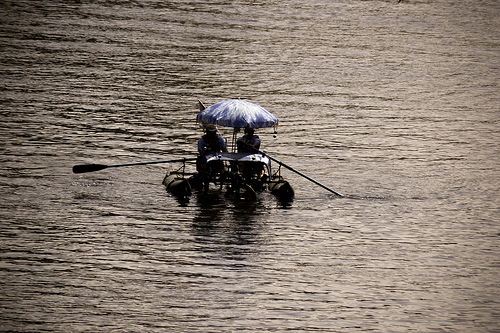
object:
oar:
[256, 147, 349, 201]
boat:
[162, 99, 298, 209]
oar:
[69, 151, 202, 177]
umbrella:
[195, 97, 283, 131]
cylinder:
[265, 181, 296, 207]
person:
[230, 127, 264, 156]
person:
[194, 125, 230, 160]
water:
[0, 0, 498, 331]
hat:
[201, 124, 221, 132]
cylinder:
[159, 168, 191, 196]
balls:
[270, 131, 277, 142]